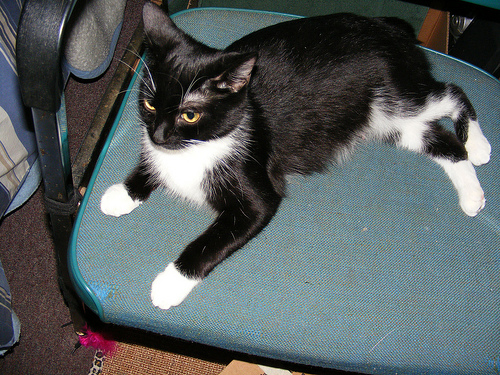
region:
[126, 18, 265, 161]
A black cat's head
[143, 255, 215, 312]
A white paw of a cat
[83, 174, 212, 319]
Two white paws of a cat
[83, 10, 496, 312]
A black cat sitting atop a computer chair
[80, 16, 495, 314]
A black cat with white paws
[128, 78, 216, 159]
A cat's face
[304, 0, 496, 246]
The lower half of a cat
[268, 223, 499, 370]
Blue fabric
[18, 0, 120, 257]
The armrest for a chair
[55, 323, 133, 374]
A rug with a leopard skin pattern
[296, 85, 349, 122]
stomach of a cat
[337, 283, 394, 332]
part of a pillow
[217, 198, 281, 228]
part of a knee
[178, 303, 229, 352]
edge of a pillow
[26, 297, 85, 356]
part of a carpet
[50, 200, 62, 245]
part of a post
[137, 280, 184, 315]
edge of a paw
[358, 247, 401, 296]
part of a cushion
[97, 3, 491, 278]
A black and white cat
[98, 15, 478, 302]
The cat is lying on a chair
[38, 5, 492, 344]
The chair has a blue seat cushion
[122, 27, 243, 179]
The cat has yellow eyes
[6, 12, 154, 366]
The carpet is brown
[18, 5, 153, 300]
The arms of the chair are black and silver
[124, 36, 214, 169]
The cat has white whiskers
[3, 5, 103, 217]
A blue and tan blanket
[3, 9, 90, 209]
The blanket is striped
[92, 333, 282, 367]
A brown woven blanket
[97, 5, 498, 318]
a plant laying on a table.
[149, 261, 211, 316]
a cat's white paw.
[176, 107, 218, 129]
the left eye of a cat.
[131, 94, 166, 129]
the right eye of a cat.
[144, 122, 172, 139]
a cat's black nose.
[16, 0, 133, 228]
a handle on a chair.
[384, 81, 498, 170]
the hind leg of a cat.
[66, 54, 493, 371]
seat on a wooden chair.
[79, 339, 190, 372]
section of a floor.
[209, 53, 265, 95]
left car ear.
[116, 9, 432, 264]
this is a cat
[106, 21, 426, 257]
the cat is black in color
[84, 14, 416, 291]
the cat is lying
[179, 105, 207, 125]
the eye is open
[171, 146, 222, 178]
the fur has white strip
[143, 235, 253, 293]
the leg is in front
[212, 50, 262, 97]
the ear is upright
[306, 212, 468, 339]
this is a sofa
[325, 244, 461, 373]
the sofa is old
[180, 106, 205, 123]
the eye is yellow in color